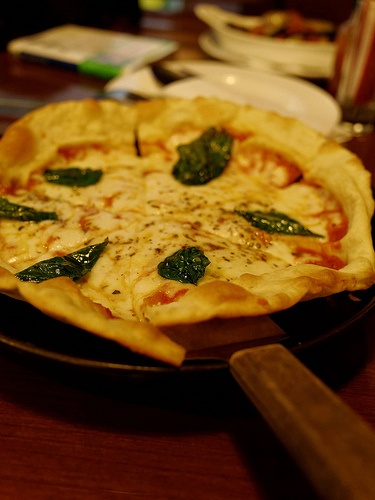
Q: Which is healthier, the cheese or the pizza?
A: The cheese is healthier than the pizza.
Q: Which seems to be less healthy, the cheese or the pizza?
A: The pizza is less healthy than the cheese.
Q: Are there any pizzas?
A: Yes, there is a pizza.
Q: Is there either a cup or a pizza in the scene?
A: Yes, there is a pizza.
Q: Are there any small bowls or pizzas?
A: Yes, there is a small pizza.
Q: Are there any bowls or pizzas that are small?
A: Yes, the pizza is small.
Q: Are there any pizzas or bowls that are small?
A: Yes, the pizza is small.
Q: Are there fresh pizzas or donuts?
A: Yes, there is a fresh pizza.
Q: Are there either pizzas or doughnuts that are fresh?
A: Yes, the pizza is fresh.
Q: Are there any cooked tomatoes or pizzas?
A: Yes, there is a cooked pizza.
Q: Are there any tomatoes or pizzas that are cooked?
A: Yes, the pizza is cooked.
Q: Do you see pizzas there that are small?
A: Yes, there is a small pizza.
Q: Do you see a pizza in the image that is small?
A: Yes, there is a pizza that is small.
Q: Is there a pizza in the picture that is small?
A: Yes, there is a pizza that is small.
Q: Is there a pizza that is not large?
A: Yes, there is a small pizza.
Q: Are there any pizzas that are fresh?
A: Yes, there is a fresh pizza.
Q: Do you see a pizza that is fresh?
A: Yes, there is a pizza that is fresh.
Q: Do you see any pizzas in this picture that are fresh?
A: Yes, there is a pizza that is fresh.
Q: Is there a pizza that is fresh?
A: Yes, there is a pizza that is fresh.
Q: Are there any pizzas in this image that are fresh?
A: Yes, there is a pizza that is fresh.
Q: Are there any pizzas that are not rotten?
A: Yes, there is a fresh pizza.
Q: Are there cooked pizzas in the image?
A: Yes, there is a cooked pizza.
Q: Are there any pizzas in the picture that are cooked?
A: Yes, there is a pizza that is cooked.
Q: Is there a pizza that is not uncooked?
A: Yes, there is an cooked pizza.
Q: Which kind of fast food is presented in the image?
A: The fast food is a pizza.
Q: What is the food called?
A: The food is a pizza.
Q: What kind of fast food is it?
A: The food is a pizza.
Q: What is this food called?
A: That is a pizza.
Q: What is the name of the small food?
A: The food is a pizza.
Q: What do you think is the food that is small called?
A: The food is a pizza.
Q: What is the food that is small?
A: The food is a pizza.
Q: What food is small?
A: The food is a pizza.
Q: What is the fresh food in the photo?
A: The food is a pizza.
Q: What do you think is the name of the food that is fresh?
A: The food is a pizza.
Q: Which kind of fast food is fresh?
A: The fast food is a pizza.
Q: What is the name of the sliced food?
A: The food is a pizza.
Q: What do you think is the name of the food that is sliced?
A: The food is a pizza.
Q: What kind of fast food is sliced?
A: The fast food is a pizza.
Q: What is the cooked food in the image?
A: The food is a pizza.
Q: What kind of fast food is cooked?
A: The fast food is a pizza.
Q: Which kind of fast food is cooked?
A: The fast food is a pizza.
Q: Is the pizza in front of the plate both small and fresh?
A: Yes, the pizza is small and fresh.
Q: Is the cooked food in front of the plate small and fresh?
A: Yes, the pizza is small and fresh.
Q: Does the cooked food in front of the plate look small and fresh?
A: Yes, the pizza is small and fresh.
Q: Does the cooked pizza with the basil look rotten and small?
A: No, the pizza is small but fresh.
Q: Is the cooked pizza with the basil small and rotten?
A: No, the pizza is small but fresh.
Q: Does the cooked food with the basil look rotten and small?
A: No, the pizza is small but fresh.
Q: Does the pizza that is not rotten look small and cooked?
A: Yes, the pizza is small and cooked.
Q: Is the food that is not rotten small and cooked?
A: Yes, the pizza is small and cooked.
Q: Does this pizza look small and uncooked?
A: No, the pizza is small but cooked.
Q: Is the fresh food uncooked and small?
A: No, the pizza is small but cooked.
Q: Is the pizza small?
A: Yes, the pizza is small.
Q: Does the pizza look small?
A: Yes, the pizza is small.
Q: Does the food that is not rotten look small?
A: Yes, the pizza is small.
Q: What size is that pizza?
A: The pizza is small.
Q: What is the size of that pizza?
A: The pizza is small.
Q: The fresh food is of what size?
A: The pizza is small.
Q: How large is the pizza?
A: The pizza is small.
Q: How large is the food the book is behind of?
A: The pizza is small.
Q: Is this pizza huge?
A: No, the pizza is small.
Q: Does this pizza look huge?
A: No, the pizza is small.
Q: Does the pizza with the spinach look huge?
A: No, the pizza is small.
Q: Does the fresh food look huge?
A: No, the pizza is small.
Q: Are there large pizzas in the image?
A: No, there is a pizza but it is small.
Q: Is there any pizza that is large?
A: No, there is a pizza but it is small.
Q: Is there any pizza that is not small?
A: No, there is a pizza but it is small.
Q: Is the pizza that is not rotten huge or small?
A: The pizza is small.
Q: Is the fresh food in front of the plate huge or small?
A: The pizza is small.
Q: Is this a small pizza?
A: Yes, this is a small pizza.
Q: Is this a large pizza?
A: No, this is a small pizza.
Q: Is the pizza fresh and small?
A: Yes, the pizza is fresh and small.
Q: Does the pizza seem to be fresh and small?
A: Yes, the pizza is fresh and small.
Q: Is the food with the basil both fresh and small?
A: Yes, the pizza is fresh and small.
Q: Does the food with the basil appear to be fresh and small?
A: Yes, the pizza is fresh and small.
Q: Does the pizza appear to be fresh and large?
A: No, the pizza is fresh but small.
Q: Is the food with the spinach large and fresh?
A: No, the pizza is fresh but small.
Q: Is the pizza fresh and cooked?
A: Yes, the pizza is fresh and cooked.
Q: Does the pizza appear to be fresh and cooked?
A: Yes, the pizza is fresh and cooked.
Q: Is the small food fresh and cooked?
A: Yes, the pizza is fresh and cooked.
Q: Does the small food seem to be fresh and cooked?
A: Yes, the pizza is fresh and cooked.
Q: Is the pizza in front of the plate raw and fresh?
A: No, the pizza is fresh but cooked.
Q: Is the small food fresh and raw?
A: No, the pizza is fresh but cooked.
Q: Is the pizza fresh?
A: Yes, the pizza is fresh.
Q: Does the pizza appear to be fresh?
A: Yes, the pizza is fresh.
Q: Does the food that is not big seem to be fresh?
A: Yes, the pizza is fresh.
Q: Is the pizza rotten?
A: No, the pizza is fresh.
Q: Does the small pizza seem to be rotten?
A: No, the pizza is fresh.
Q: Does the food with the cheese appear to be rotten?
A: No, the pizza is fresh.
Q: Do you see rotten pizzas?
A: No, there is a pizza but it is fresh.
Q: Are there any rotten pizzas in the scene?
A: No, there is a pizza but it is fresh.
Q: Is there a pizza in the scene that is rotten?
A: No, there is a pizza but it is fresh.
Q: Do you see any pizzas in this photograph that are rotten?
A: No, there is a pizza but it is fresh.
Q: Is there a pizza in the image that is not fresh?
A: No, there is a pizza but it is fresh.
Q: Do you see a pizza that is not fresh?
A: No, there is a pizza but it is fresh.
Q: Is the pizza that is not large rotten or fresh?
A: The pizza is fresh.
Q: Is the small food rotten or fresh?
A: The pizza is fresh.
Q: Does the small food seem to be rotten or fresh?
A: The pizza is fresh.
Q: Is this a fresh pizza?
A: Yes, this is a fresh pizza.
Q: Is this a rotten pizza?
A: No, this is a fresh pizza.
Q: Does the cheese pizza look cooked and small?
A: Yes, the pizza is cooked and small.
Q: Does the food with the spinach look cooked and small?
A: Yes, the pizza is cooked and small.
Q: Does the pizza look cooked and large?
A: No, the pizza is cooked but small.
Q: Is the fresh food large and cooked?
A: No, the pizza is cooked but small.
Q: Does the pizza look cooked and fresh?
A: Yes, the pizza is cooked and fresh.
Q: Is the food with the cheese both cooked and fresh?
A: Yes, the pizza is cooked and fresh.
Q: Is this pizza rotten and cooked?
A: No, the pizza is cooked but fresh.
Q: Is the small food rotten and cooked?
A: No, the pizza is cooked but fresh.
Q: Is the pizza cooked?
A: Yes, the pizza is cooked.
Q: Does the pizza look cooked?
A: Yes, the pizza is cooked.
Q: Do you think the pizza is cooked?
A: Yes, the pizza is cooked.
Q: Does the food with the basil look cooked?
A: Yes, the pizza is cooked.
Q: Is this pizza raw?
A: No, the pizza is cooked.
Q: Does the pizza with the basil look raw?
A: No, the pizza is cooked.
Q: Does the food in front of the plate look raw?
A: No, the pizza is cooked.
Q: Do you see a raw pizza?
A: No, there is a pizza but it is cooked.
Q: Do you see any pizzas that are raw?
A: No, there is a pizza but it is cooked.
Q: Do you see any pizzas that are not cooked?
A: No, there is a pizza but it is cooked.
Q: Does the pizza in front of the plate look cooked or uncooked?
A: The pizza is cooked.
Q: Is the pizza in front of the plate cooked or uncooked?
A: The pizza is cooked.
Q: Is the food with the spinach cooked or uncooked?
A: The pizza is cooked.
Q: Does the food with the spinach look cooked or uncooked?
A: The pizza is cooked.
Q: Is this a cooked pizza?
A: Yes, this is a cooked pizza.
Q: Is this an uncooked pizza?
A: No, this is a cooked pizza.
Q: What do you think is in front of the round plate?
A: The pizza is in front of the plate.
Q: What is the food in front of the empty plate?
A: The food is a pizza.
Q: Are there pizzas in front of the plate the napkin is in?
A: Yes, there is a pizza in front of the plate.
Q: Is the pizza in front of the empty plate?
A: Yes, the pizza is in front of the plate.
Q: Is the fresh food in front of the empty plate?
A: Yes, the pizza is in front of the plate.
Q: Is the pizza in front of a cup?
A: No, the pizza is in front of the plate.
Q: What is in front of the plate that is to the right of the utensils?
A: The pizza is in front of the plate.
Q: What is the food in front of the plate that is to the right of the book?
A: The food is a pizza.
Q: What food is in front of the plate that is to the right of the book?
A: The food is a pizza.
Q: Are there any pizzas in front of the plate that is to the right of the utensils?
A: Yes, there is a pizza in front of the plate.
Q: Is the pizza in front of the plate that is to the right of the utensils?
A: Yes, the pizza is in front of the plate.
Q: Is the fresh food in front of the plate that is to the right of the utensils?
A: Yes, the pizza is in front of the plate.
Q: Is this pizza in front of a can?
A: No, the pizza is in front of the plate.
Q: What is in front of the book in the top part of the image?
A: The pizza is in front of the book.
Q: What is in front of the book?
A: The pizza is in front of the book.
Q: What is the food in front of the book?
A: The food is a pizza.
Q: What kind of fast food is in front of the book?
A: The food is a pizza.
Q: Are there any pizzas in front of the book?
A: Yes, there is a pizza in front of the book.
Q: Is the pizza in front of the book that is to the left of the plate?
A: Yes, the pizza is in front of the book.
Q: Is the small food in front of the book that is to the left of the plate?
A: Yes, the pizza is in front of the book.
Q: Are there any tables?
A: Yes, there is a table.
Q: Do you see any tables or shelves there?
A: Yes, there is a table.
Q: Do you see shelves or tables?
A: Yes, there is a table.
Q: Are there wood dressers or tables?
A: Yes, there is a wood table.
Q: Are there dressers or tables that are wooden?
A: Yes, the table is wooden.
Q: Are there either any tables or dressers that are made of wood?
A: Yes, the table is made of wood.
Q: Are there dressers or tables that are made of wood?
A: Yes, the table is made of wood.